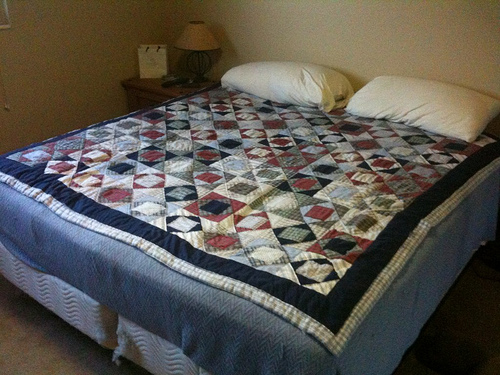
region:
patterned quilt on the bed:
[128, 132, 353, 268]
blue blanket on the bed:
[148, 285, 233, 339]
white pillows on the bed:
[249, 53, 473, 131]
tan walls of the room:
[323, 2, 451, 52]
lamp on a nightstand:
[181, 18, 220, 80]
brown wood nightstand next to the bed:
[129, 82, 166, 97]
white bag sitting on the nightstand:
[133, 42, 171, 79]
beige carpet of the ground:
[16, 316, 80, 369]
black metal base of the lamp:
[180, 53, 217, 78]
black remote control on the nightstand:
[160, 77, 188, 90]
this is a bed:
[71, 130, 339, 310]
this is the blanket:
[201, 100, 331, 214]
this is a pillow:
[400, 80, 452, 105]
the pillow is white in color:
[378, 83, 430, 113]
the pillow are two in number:
[225, 59, 472, 136]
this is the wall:
[40, 15, 87, 101]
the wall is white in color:
[311, 12, 431, 63]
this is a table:
[130, 72, 165, 90]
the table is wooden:
[131, 71, 153, 90]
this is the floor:
[5, 318, 52, 368]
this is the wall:
[294, 10, 376, 42]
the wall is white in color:
[348, 13, 450, 55]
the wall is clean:
[35, 13, 77, 88]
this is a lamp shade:
[175, 20, 223, 69]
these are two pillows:
[217, 62, 494, 142]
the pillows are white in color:
[301, 80, 388, 100]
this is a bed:
[36, 108, 486, 366]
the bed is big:
[26, 117, 498, 372]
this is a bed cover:
[118, 125, 264, 270]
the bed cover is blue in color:
[71, 235, 103, 277]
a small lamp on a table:
[179, 19, 217, 102]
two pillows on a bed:
[214, 35, 488, 112]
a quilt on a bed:
[1, 77, 464, 236]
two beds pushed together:
[68, 274, 161, 374]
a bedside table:
[118, 63, 219, 114]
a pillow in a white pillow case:
[350, 83, 496, 153]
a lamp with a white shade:
[174, 17, 226, 86]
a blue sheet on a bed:
[286, 234, 461, 372]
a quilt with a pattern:
[171, 131, 398, 315]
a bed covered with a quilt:
[10, 79, 482, 311]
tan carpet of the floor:
[20, 328, 79, 367]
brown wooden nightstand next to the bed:
[129, 82, 169, 107]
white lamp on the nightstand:
[177, 18, 218, 84]